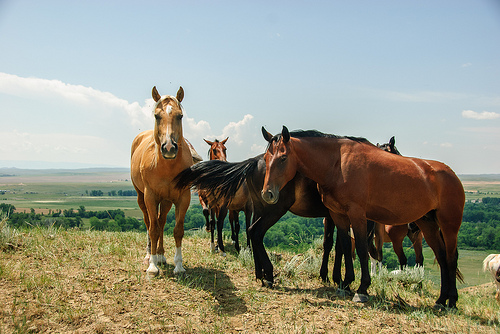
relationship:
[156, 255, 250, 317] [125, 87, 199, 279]
shadow of horse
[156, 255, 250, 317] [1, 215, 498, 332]
shadow on ground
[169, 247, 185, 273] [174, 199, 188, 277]
sock on leg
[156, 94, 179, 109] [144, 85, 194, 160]
forelock on head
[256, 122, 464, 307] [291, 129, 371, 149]
horse with a mane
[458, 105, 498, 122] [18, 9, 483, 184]
cloud in sky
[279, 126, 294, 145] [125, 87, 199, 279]
ear on a horse